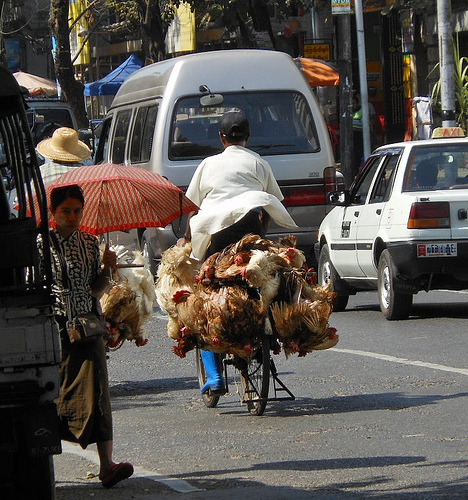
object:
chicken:
[222, 293, 265, 362]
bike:
[196, 325, 294, 416]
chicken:
[279, 246, 306, 269]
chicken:
[272, 272, 328, 350]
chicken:
[171, 338, 195, 359]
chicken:
[194, 252, 215, 286]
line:
[326, 345, 467, 379]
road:
[55, 290, 467, 499]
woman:
[36, 185, 132, 487]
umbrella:
[14, 162, 201, 281]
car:
[313, 137, 468, 320]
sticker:
[417, 242, 460, 258]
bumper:
[388, 241, 467, 277]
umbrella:
[85, 53, 145, 94]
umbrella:
[12, 70, 57, 95]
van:
[94, 49, 337, 262]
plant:
[425, 14, 467, 125]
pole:
[435, 0, 458, 126]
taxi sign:
[431, 126, 465, 139]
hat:
[218, 112, 250, 139]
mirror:
[200, 84, 225, 107]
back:
[153, 49, 336, 269]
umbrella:
[295, 55, 338, 86]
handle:
[102, 183, 114, 282]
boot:
[200, 350, 225, 392]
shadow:
[215, 391, 467, 416]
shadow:
[109, 368, 294, 411]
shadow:
[344, 302, 467, 320]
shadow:
[55, 455, 467, 499]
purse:
[50, 231, 107, 342]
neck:
[55, 226, 73, 238]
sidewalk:
[0, 0, 467, 191]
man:
[184, 112, 298, 395]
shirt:
[187, 145, 298, 259]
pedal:
[207, 358, 235, 396]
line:
[62, 440, 214, 495]